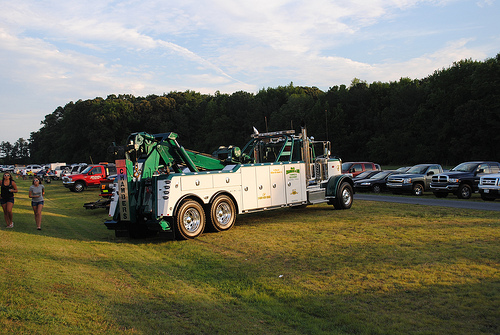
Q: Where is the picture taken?
A: A field.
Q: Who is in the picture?
A: Two women.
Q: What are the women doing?
A: Running.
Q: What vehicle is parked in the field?
A: A towing truck.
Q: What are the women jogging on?
A: Grass.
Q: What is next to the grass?
A: A parking lot.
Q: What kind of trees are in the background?
A: Spruce trees.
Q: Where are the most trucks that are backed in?
A: On the right side of the street.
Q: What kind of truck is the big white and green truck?
A: A tow truck.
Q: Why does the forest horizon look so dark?
A: The trees provide a very dense canopy.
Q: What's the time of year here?
A: Summer.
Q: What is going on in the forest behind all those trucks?
A: A pervert is looking at the women in short shorts walking by.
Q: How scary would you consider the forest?
A: Very scary.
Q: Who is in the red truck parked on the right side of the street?
A: The truck is empty.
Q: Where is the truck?
A: In the grass.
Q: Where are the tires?
A: In the grass.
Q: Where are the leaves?
A: On the grass.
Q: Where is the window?
A: On the car.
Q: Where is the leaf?
A: On the tree.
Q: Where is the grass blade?
A: On the ground.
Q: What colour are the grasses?
A: Green.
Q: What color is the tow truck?
A: Green & white.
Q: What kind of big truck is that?
A: Tow truck.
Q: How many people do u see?
A: 2.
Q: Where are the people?
A: To the left.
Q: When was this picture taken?
A: Daytime.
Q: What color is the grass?
A: Green.